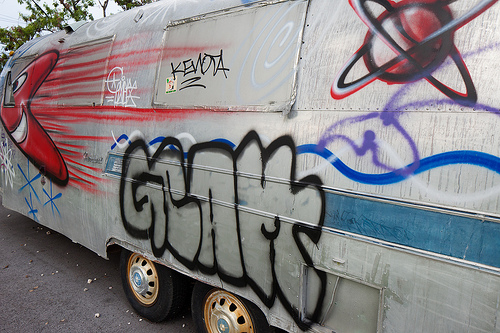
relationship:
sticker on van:
[160, 74, 180, 93] [1, 1, 499, 331]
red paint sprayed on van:
[24, 42, 211, 189] [1, 1, 499, 331]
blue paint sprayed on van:
[110, 130, 498, 187] [1, 1, 499, 331]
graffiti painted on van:
[97, 122, 328, 328] [1, 1, 499, 331]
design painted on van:
[4, 36, 74, 183] [1, 1, 499, 331]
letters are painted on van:
[95, 56, 145, 101] [1, 1, 499, 331]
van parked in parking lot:
[1, 1, 499, 331] [4, 206, 244, 331]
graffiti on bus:
[115, 128, 327, 327] [8, 0, 498, 331]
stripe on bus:
[304, 188, 499, 265] [8, 0, 498, 331]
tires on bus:
[115, 241, 261, 330] [8, 0, 498, 331]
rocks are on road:
[76, 251, 116, 329] [2, 211, 222, 331]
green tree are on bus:
[2, 1, 67, 32] [8, 0, 498, 331]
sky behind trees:
[2, 0, 119, 59] [1, 1, 155, 56]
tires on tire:
[118, 248, 192, 324] [128, 245, 168, 310]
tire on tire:
[179, 275, 258, 331] [190, 281, 269, 333]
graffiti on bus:
[166, 48, 236, 88] [8, 0, 498, 331]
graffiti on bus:
[326, 0, 496, 102] [8, 0, 498, 331]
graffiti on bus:
[1, 48, 74, 179] [8, 0, 498, 331]